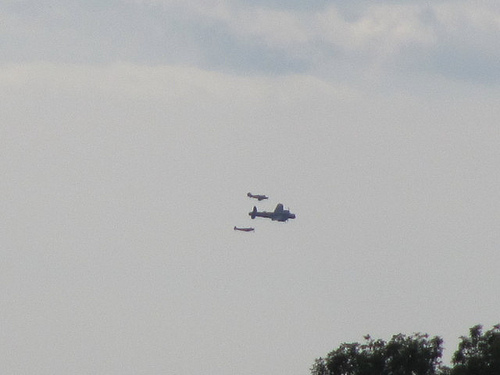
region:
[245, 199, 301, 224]
an airplane in the sky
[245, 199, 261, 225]
two tailwings on the plane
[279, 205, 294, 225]
propellers on the plane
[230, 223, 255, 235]
a flatter plane in the distance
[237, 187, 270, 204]
this plane is higher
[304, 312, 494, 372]
trees below the airplanes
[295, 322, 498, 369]
the trees have green leaves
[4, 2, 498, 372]
grey clouds in the sky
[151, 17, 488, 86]
blue patches in the clouds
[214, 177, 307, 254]
the airplanes are grey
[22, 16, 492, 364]
the sky is blue with white clouds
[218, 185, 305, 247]
three planes are flying in formation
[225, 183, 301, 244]
the planes have propellers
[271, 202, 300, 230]
the plane has two propellars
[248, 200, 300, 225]
the propellers are on the wings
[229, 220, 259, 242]
a propeller is on the nose of the plane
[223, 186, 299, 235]
the three planes are gray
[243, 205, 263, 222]
the tail of the twin propeller plane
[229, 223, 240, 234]
the tail of the smaller plane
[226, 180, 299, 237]
planes are flying near the larger plane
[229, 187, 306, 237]
The three gray aircraft.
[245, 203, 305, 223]
The high flying biggest aircraft.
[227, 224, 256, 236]
The small aircraft on the left.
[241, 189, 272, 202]
The small aircraft on the right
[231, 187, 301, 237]
Trio aircraft flying in a clear sky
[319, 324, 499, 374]
The tree tops on the right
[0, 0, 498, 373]
The gray clear sky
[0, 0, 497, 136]
Clouds high above the sky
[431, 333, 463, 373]
The gap between the trees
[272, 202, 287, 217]
The right plane wing.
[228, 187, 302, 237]
three old airplanes perform a flyover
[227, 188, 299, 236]
a large warplane is flanked by two smaller planes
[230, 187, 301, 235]
two small classic warplanes follow a larger one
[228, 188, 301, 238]
three classic aircraft perform at a show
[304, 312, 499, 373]
trees under a grey overcast sky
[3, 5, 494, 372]
sky is overcast and grey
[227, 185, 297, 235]
a collection of classic war planes flying overhead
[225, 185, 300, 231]
classic warplanes are silhouetted against a grey sky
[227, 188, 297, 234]
a large classic warplane leading two smaller ones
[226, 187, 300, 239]
two small propeller planes flank a larger plane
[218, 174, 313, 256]
Three planes flying in formation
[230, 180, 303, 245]
One large plane between two smaller planes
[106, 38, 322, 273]
Planes flying on cloudy day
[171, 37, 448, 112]
Dark gray clouds in the sky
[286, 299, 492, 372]
Dark trees on cloudy day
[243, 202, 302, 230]
One large plane in the sky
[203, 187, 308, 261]
One large plane followed by two small planes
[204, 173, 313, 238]
Airplanes in an airshow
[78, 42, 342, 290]
Planes in airshow on cloudy day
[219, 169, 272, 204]
Small plane flying